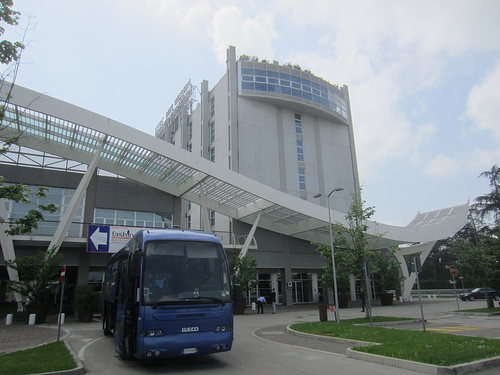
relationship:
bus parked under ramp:
[98, 226, 238, 367] [10, 77, 483, 318]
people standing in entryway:
[257, 288, 277, 313] [239, 271, 271, 305]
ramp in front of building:
[2, 81, 485, 242] [6, 42, 378, 307]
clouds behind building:
[347, 2, 498, 225] [152, 68, 388, 218]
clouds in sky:
[347, 2, 498, 225] [104, 0, 490, 189]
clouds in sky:
[99, 2, 499, 227] [1, 2, 498, 226]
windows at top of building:
[238, 67, 348, 117] [153, 44, 369, 304]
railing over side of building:
[5, 80, 472, 243] [2, 38, 497, 323]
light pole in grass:
[313, 185, 346, 324] [289, 314, 498, 366]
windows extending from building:
[238, 67, 348, 117] [153, 44, 369, 304]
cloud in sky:
[2, 1, 492, 234] [423, 78, 472, 154]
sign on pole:
[57, 264, 69, 283] [55, 280, 66, 344]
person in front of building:
[268, 287, 283, 315] [205, 48, 377, 303]